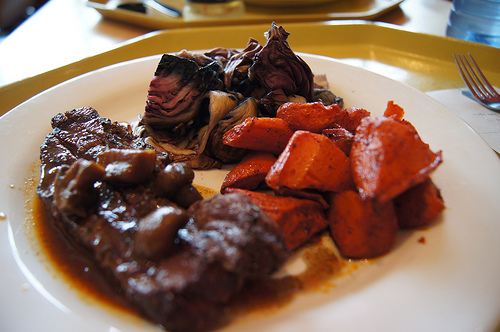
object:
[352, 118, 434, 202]
carrot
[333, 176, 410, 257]
carrot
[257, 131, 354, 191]
carrot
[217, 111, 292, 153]
carrot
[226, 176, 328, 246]
carrot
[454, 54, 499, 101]
silver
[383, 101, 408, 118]
yams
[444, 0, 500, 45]
bottle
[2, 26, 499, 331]
clouds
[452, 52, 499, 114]
fork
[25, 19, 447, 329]
food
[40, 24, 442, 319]
food items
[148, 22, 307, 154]
cabbage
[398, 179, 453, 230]
carrots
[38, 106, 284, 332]
glaze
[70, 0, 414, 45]
tray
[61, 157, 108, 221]
mushrooms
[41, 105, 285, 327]
meat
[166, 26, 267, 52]
fence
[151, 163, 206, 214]
mushrooms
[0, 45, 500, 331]
plate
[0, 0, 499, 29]
background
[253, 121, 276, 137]
orange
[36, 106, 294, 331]
another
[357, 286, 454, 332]
first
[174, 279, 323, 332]
sauce